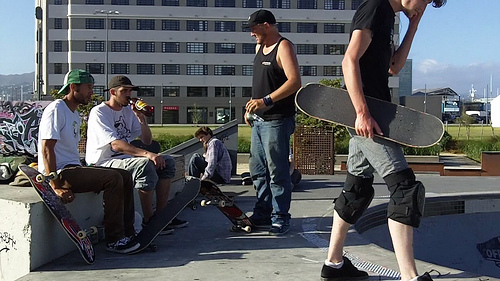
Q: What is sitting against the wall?
A: Skateboard.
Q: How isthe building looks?
A: Many windows.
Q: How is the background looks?
A: Trimmed grass.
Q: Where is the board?
A: In hand.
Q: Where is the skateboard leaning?
A: A wall.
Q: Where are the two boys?
A: On wall.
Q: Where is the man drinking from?
A: A bottle.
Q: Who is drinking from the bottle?
A: A man.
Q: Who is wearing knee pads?
A: A man.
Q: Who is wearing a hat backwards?
A: A boy.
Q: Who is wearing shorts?
A: A man.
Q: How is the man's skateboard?
A: Black.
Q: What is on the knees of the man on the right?
A: Knee pads.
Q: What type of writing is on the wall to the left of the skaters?
A: Graffiti.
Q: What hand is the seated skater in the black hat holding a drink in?
A: Left.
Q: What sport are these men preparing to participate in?
A: Skateboarding.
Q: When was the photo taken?
A: Daytime.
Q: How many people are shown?
A: Five.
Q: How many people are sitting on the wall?
A: Two.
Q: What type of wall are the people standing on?
A: Concrete.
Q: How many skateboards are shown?
A: Four.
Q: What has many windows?
A: Building.